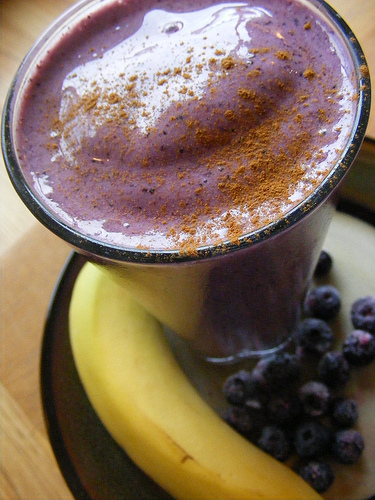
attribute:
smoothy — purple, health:
[17, 3, 355, 249]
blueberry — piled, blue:
[299, 317, 337, 357]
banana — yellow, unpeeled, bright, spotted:
[67, 262, 331, 499]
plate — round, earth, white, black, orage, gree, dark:
[41, 133, 374, 498]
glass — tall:
[4, 3, 371, 363]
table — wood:
[4, 2, 375, 497]